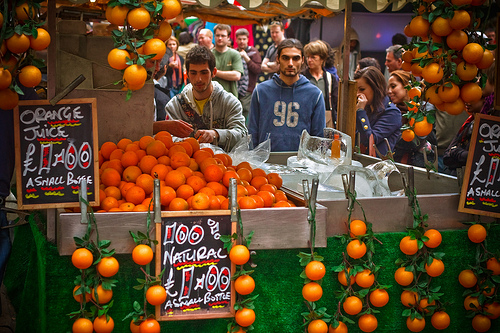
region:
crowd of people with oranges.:
[50, 25, 445, 270]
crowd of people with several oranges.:
[30, 25, 465, 290]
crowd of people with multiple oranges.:
[41, 21, 471, 291]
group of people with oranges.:
[25, 15, 466, 307]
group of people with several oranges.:
[52, 16, 452, 316]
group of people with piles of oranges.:
[46, 30, 456, 301]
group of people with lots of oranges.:
[35, 20, 470, 300]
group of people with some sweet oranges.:
[16, 10, 471, 315]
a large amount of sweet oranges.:
[115, 132, 275, 203]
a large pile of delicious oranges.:
[115, 132, 272, 208]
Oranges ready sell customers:
[62, 51, 465, 289]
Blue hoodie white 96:
[246, 47, 324, 147]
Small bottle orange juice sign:
[11, 99, 101, 204]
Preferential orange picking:
[157, 41, 244, 151]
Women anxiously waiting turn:
[349, 56, 426, 155]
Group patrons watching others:
[170, 18, 285, 58]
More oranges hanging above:
[402, 3, 499, 148]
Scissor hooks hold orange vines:
[301, 170, 443, 320]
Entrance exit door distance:
[352, 12, 403, 63]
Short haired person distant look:
[300, 38, 331, 82]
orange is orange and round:
[89, 129, 292, 216]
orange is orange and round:
[298, 257, 325, 311]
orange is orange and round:
[124, 148, 166, 192]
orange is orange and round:
[172, 165, 212, 210]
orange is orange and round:
[200, 137, 248, 217]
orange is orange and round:
[88, 140, 155, 227]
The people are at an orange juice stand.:
[147, 30, 439, 160]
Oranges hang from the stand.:
[300, 202, 443, 331]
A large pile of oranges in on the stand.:
[61, 123, 286, 226]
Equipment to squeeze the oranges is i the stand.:
[242, 120, 408, 208]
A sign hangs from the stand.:
[145, 197, 257, 325]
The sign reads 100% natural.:
[157, 211, 230, 268]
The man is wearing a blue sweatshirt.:
[240, 67, 334, 156]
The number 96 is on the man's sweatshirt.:
[260, 96, 310, 131]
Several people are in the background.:
[124, 4, 314, 94]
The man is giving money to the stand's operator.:
[152, 107, 215, 157]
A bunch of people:
[145, 23, 446, 182]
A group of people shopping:
[117, 27, 476, 208]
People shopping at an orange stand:
[141, 37, 438, 309]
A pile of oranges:
[63, 120, 295, 254]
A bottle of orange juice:
[305, 126, 354, 186]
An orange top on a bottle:
[324, 130, 347, 142]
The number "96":
[264, 99, 312, 142]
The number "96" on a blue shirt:
[262, 42, 333, 161]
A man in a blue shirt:
[254, 34, 326, 158]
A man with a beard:
[270, 39, 325, 84]